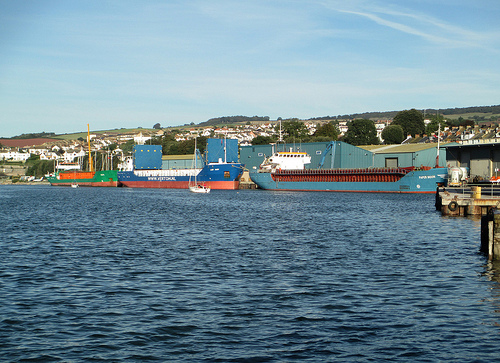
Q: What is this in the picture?
A: The sky.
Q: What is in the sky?
A: It has some clouds.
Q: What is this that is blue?
A: The water.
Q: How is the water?
A: The water has ripples.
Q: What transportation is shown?
A: Boats.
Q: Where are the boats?
A: In water.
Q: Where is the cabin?
A: No cabin.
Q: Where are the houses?
A: On hill behind boats.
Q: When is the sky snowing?
A: No snow.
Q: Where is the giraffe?
A: No giraffe.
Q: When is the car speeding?
A: No car.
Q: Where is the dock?
A: On the right.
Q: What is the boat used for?
A: Transporting materials.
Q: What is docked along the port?
A: 3 boats.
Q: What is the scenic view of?
A: Coastal town.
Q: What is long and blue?
A: Boat.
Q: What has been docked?
A: 3 boats.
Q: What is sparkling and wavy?
A: Ocean.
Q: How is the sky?
A: Blue with few clouds.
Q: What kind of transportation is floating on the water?
A: Boats.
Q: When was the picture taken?
A: Daytime.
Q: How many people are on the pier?
A: None.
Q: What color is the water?
A: Dark blue.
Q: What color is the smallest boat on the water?
A: White.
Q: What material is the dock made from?
A: Wood.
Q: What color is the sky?
A: Blue.